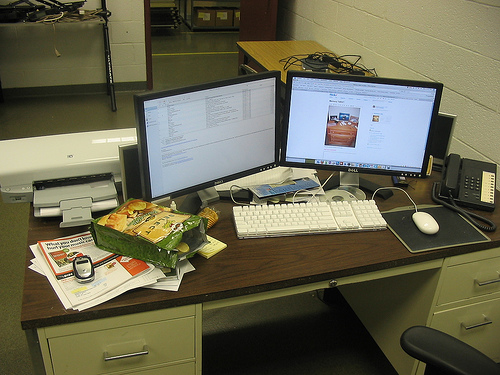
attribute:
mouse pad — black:
[381, 197, 493, 252]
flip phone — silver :
[58, 249, 102, 296]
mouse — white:
[411, 209, 441, 238]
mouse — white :
[410, 208, 442, 235]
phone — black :
[428, 151, 497, 234]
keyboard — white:
[232, 197, 390, 240]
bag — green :
[81, 177, 221, 300]